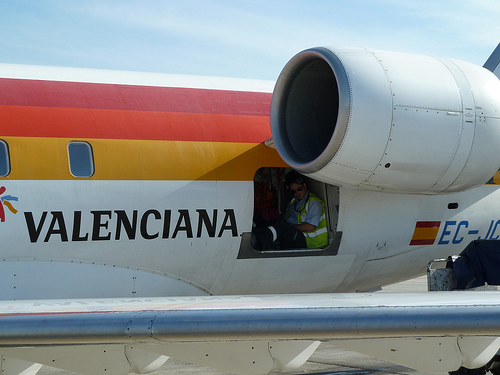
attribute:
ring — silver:
[270, 46, 348, 171]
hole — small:
[253, 167, 334, 261]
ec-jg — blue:
[435, 214, 498, 244]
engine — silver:
[262, 40, 498, 192]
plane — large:
[4, 29, 498, 372]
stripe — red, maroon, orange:
[6, 82, 284, 191]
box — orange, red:
[404, 213, 445, 247]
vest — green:
[292, 204, 326, 256]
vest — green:
[286, 198, 329, 252]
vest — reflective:
[288, 198, 333, 250]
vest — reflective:
[281, 189, 328, 245]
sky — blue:
[2, 0, 498, 69]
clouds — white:
[1, 4, 499, 78]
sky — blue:
[4, 2, 498, 82]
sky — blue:
[2, 2, 498, 94]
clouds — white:
[1, 2, 497, 69]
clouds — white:
[4, 2, 496, 89]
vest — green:
[279, 198, 333, 248]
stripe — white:
[301, 225, 326, 243]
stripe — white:
[266, 222, 282, 247]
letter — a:
[48, 207, 71, 251]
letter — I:
[160, 198, 170, 238]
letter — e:
[87, 196, 110, 256]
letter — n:
[155, 196, 177, 253]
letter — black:
[40, 201, 264, 285]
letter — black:
[30, 197, 238, 265]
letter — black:
[27, 190, 231, 275]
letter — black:
[16, 199, 239, 254]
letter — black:
[19, 217, 241, 248]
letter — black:
[25, 200, 235, 252]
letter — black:
[20, 196, 242, 257]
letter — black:
[31, 207, 253, 257]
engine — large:
[257, 42, 498, 209]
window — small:
[64, 134, 96, 177]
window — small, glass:
[61, 136, 101, 183]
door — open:
[250, 167, 344, 261]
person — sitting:
[284, 187, 325, 237]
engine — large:
[259, 33, 499, 200]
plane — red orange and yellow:
[48, 58, 444, 336]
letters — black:
[15, 183, 251, 267]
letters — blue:
[434, 205, 476, 264]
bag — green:
[293, 207, 360, 257]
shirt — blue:
[265, 183, 330, 225]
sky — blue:
[63, 14, 232, 84]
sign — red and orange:
[31, 166, 223, 264]